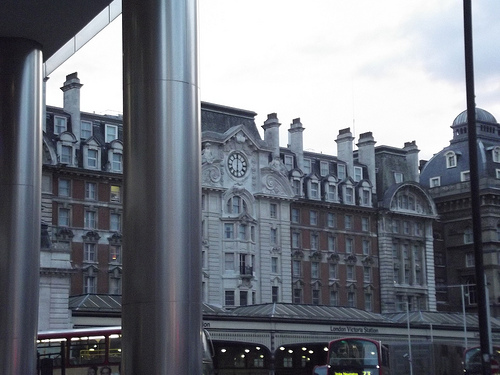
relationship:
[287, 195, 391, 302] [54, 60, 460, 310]
windows on building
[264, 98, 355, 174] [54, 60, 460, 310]
chimney on building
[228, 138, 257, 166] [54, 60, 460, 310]
clock on building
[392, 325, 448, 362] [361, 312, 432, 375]
lights on entry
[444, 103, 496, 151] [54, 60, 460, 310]
dome on building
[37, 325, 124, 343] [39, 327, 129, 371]
light on inside bus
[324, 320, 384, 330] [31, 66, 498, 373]
london written on building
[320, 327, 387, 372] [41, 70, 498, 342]
bus passing in front building